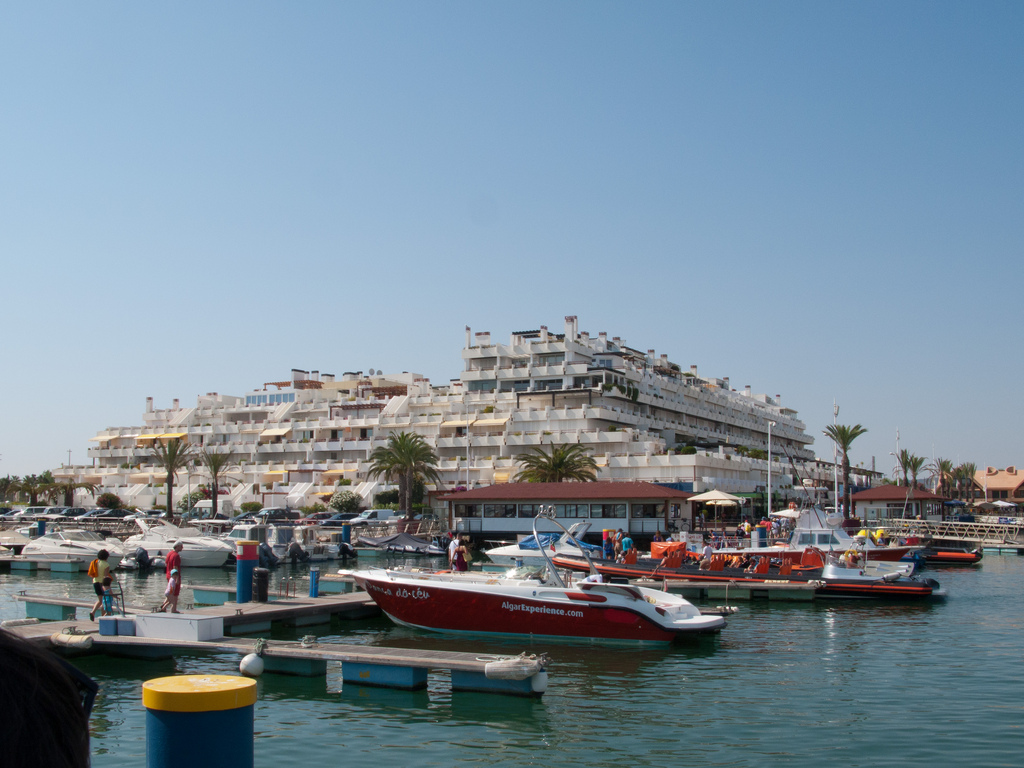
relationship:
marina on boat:
[0, 515, 1022, 766] [26, 531, 128, 558]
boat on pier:
[23, 531, 119, 564] [20, 304, 1017, 765]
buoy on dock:
[233, 641, 273, 677] [2, 575, 550, 699]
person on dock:
[163, 569, 180, 612] [1, 588, 376, 637]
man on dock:
[162, 536, 189, 613] [1, 588, 376, 637]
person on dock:
[90, 550, 122, 614] [1, 588, 376, 637]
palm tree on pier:
[150, 436, 193, 522] [23, 422, 911, 708]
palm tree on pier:
[197, 448, 236, 513] [23, 422, 911, 708]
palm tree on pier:
[365, 433, 446, 517] [23, 422, 911, 708]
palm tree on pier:
[514, 436, 607, 487] [23, 422, 911, 708]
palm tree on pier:
[822, 419, 868, 525] [23, 422, 911, 708]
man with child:
[162, 536, 189, 613] [160, 557, 183, 616]